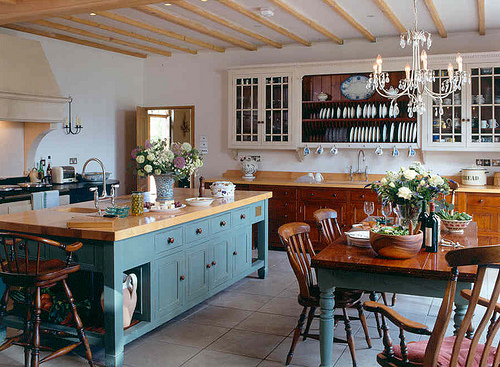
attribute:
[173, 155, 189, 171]
flower — purple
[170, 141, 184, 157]
flower — purple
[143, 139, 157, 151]
flower — purple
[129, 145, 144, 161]
flower — purple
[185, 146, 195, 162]
flower — purple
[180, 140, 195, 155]
flower — white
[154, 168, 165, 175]
flower — white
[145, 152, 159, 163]
flower — white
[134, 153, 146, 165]
flower — white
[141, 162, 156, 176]
flower — white